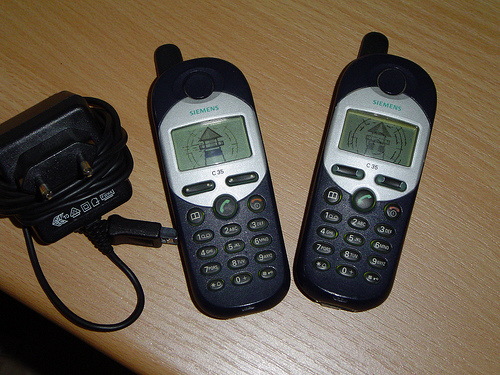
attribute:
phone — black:
[295, 32, 438, 313]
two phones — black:
[150, 31, 437, 319]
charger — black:
[0, 91, 180, 331]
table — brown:
[0, 0, 500, 374]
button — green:
[354, 189, 376, 212]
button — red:
[385, 202, 401, 219]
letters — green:
[371, 99, 404, 113]